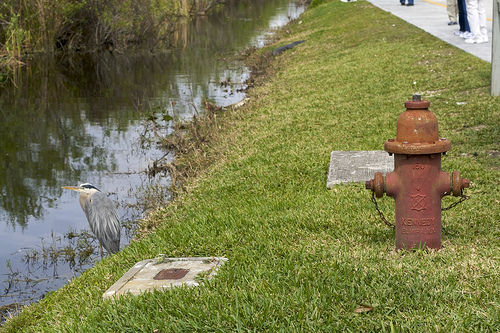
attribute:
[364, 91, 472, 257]
fire hydrant — red, rusty red, pink, faded, old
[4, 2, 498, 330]
grass — green, brown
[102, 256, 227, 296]
concrete block — gray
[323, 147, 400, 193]
concrete block — gray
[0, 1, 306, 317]
water — calm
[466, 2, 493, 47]
pants — white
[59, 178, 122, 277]
bird — gray, white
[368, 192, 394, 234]
chain — rusty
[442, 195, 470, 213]
chain — rusty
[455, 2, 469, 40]
pants — black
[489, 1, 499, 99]
post — gray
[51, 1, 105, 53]
tree — dead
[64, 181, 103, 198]
head — white